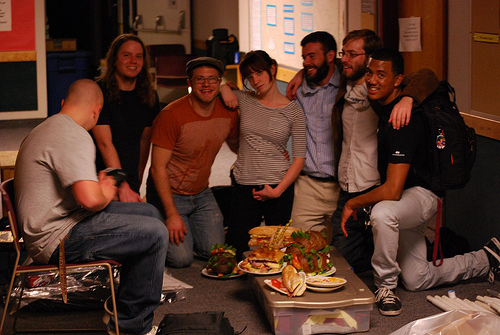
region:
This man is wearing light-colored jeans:
[376, 228, 412, 305]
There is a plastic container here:
[281, 292, 300, 332]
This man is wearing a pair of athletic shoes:
[373, 290, 393, 332]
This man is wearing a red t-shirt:
[178, 128, 197, 216]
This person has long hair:
[116, 34, 142, 71]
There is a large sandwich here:
[253, 248, 263, 275]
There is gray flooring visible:
[223, 290, 233, 312]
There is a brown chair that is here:
[8, 248, 45, 313]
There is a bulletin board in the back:
[21, 53, 47, 163]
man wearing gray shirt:
[18, 112, 103, 234]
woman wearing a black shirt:
[91, 79, 156, 183]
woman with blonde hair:
[91, 35, 153, 95]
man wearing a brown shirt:
[148, 91, 228, 202]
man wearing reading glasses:
[183, 67, 225, 88]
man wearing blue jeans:
[153, 185, 222, 257]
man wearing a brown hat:
[186, 55, 221, 72]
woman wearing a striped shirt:
[228, 85, 310, 188]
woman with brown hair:
[236, 43, 278, 89]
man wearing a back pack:
[406, 73, 475, 187]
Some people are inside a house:
[11, 8, 476, 323]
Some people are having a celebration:
[15, 7, 480, 330]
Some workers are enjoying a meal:
[21, 17, 487, 328]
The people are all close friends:
[11, 8, 477, 321]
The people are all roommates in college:
[11, 13, 493, 333]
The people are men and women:
[10, 3, 480, 319]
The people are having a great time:
[10, 15, 482, 315]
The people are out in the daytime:
[16, 16, 486, 313]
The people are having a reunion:
[5, 21, 475, 311]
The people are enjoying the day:
[28, 21, 478, 312]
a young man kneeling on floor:
[145, 55, 238, 267]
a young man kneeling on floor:
[291, 31, 341, 235]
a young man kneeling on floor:
[333, 27, 385, 264]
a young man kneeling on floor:
[335, 47, 499, 317]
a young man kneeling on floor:
[86, 33, 156, 199]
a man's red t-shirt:
[150, 94, 237, 189]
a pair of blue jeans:
[155, 185, 227, 267]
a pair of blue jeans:
[47, 198, 167, 329]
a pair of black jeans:
[227, 179, 293, 253]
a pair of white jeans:
[370, 187, 487, 292]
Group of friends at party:
[12, 20, 483, 315]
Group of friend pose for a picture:
[15, 21, 485, 306]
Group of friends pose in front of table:
[1, 20, 478, 320]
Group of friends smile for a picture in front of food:
[5, 17, 490, 322]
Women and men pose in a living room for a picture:
[5, 15, 485, 330]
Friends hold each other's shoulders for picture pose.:
[5, 20, 480, 330]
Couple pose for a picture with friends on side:
[150, 25, 495, 330]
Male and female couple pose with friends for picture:
[155, 25, 495, 326]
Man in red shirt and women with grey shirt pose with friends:
[147, 5, 497, 333]